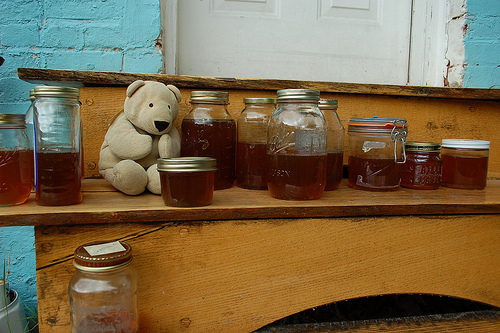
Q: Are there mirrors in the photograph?
A: No, there are no mirrors.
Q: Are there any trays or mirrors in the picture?
A: No, there are no mirrors or trays.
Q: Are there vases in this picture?
A: No, there are no vases.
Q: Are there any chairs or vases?
A: No, there are no vases or chairs.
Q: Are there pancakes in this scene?
A: No, there are no pancakes.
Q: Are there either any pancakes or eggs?
A: No, there are no pancakes or eggs.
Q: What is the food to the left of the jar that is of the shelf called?
A: The food is honey.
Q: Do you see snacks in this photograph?
A: No, there are no snacks.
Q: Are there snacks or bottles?
A: No, there are no snacks or bottles.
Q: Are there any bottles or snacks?
A: No, there are no snacks or bottles.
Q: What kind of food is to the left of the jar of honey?
A: The food is honey.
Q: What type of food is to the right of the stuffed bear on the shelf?
A: The food is honey.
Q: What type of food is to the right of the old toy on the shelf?
A: The food is honey.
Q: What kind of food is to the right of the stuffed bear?
A: The food is honey.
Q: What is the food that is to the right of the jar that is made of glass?
A: The food is honey.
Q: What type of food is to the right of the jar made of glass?
A: The food is honey.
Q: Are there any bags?
A: No, there are no bags.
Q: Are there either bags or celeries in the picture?
A: No, there are no bags or celeries.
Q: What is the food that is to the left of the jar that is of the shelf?
A: The food is honey.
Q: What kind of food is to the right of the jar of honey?
A: The food is honey.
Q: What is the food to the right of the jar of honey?
A: The food is honey.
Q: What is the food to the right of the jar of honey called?
A: The food is honey.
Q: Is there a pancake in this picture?
A: No, there are no pancakes.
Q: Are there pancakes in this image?
A: No, there are no pancakes.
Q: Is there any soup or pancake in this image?
A: No, there are no pancakes or soup.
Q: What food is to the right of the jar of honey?
A: The food is honey.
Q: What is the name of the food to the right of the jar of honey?
A: The food is honey.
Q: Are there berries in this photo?
A: No, there are no berries.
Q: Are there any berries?
A: No, there are no berries.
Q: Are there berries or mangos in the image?
A: No, there are no berries or mangos.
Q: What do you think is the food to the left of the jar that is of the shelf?
A: The food is honey.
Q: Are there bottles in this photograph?
A: No, there are no bottles.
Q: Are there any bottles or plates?
A: No, there are no bottles or plates.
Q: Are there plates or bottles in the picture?
A: No, there are no bottles or plates.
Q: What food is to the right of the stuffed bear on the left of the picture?
A: The food is honey.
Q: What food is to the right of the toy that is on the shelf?
A: The food is honey.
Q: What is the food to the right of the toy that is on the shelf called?
A: The food is honey.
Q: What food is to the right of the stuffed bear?
A: The food is honey.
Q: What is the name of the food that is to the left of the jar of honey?
A: The food is honey.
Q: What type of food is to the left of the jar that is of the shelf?
A: The food is honey.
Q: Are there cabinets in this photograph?
A: No, there are no cabinets.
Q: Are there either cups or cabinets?
A: No, there are no cabinets or cups.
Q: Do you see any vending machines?
A: No, there are no vending machines.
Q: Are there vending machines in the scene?
A: No, there are no vending machines.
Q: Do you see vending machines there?
A: No, there are no vending machines.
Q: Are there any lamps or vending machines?
A: No, there are no vending machines or lamps.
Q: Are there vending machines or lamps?
A: No, there are no vending machines or lamps.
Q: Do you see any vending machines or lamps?
A: No, there are no vending machines or lamps.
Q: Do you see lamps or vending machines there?
A: No, there are no vending machines or lamps.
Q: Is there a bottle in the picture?
A: No, there are no bottles.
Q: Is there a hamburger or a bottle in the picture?
A: No, there are no bottles or hamburgers.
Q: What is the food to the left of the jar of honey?
A: The food is honey.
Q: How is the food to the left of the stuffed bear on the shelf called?
A: The food is honey.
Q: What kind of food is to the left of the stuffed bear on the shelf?
A: The food is honey.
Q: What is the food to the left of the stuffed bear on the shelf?
A: The food is honey.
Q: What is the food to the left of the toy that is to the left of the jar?
A: The food is honey.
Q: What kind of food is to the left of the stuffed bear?
A: The food is honey.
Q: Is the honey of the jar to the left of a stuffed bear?
A: Yes, the honey is to the left of a stuffed bear.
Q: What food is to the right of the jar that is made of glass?
A: The food is honey.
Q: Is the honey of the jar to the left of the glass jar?
A: No, the honey is to the right of the jar.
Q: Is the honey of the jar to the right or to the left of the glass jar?
A: The honey is to the right of the jar.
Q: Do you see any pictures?
A: No, there are no pictures.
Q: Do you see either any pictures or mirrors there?
A: No, there are no pictures or mirrors.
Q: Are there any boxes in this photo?
A: No, there are no boxes.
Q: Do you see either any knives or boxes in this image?
A: No, there are no boxes or knives.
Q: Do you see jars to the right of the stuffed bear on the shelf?
A: Yes, there is a jar to the right of the stuffed bear.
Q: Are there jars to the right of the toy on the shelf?
A: Yes, there is a jar to the right of the stuffed bear.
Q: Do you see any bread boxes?
A: No, there are no bread boxes.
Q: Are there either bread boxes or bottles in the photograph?
A: No, there are no bread boxes or bottles.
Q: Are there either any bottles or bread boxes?
A: No, there are no bread boxes or bottles.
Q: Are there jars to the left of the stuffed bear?
A: Yes, there is a jar to the left of the stuffed bear.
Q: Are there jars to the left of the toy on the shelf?
A: Yes, there is a jar to the left of the stuffed bear.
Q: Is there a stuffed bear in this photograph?
A: Yes, there is a stuffed bear.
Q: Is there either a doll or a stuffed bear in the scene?
A: Yes, there is a stuffed bear.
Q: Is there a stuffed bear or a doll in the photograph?
A: Yes, there is a stuffed bear.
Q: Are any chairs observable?
A: No, there are no chairs.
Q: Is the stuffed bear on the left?
A: Yes, the stuffed bear is on the left of the image.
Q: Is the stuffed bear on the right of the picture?
A: No, the stuffed bear is on the left of the image.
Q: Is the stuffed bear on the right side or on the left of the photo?
A: The stuffed bear is on the left of the image.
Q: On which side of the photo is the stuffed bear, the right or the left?
A: The stuffed bear is on the left of the image.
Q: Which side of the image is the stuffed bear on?
A: The stuffed bear is on the left of the image.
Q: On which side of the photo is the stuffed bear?
A: The stuffed bear is on the left of the image.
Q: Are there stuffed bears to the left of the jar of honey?
A: Yes, there is a stuffed bear to the left of the jar.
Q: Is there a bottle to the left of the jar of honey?
A: No, there is a stuffed bear to the left of the jar.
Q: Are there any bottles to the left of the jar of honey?
A: No, there is a stuffed bear to the left of the jar.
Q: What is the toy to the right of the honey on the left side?
A: The toy is a stuffed bear.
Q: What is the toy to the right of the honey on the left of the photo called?
A: The toy is a stuffed bear.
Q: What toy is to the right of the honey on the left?
A: The toy is a stuffed bear.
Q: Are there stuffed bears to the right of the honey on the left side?
A: Yes, there is a stuffed bear to the right of the honey.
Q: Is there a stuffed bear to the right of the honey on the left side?
A: Yes, there is a stuffed bear to the right of the honey.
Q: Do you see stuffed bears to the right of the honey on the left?
A: Yes, there is a stuffed bear to the right of the honey.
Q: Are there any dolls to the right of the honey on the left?
A: No, there is a stuffed bear to the right of the honey.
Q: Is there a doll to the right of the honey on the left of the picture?
A: No, there is a stuffed bear to the right of the honey.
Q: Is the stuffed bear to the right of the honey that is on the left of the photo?
A: Yes, the stuffed bear is to the right of the honey.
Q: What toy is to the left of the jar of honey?
A: The toy is a stuffed bear.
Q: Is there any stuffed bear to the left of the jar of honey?
A: Yes, there is a stuffed bear to the left of the jar.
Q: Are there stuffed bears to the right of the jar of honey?
A: Yes, there is a stuffed bear to the right of the jar.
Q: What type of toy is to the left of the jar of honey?
A: The toy is a stuffed bear.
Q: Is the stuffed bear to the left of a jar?
A: Yes, the stuffed bear is to the left of a jar.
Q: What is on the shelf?
A: The stuffed bear is on the shelf.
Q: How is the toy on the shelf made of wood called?
A: The toy is a stuffed bear.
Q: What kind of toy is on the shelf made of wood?
A: The toy is a stuffed bear.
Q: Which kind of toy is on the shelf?
A: The toy is a stuffed bear.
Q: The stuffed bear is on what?
A: The stuffed bear is on the shelf.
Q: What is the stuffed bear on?
A: The stuffed bear is on the shelf.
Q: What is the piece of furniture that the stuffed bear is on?
A: The piece of furniture is a shelf.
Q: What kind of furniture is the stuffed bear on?
A: The stuffed bear is on the shelf.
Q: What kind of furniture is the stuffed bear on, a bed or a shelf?
A: The stuffed bear is on a shelf.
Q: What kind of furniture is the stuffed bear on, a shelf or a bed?
A: The stuffed bear is on a shelf.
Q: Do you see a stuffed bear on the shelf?
A: Yes, there is a stuffed bear on the shelf.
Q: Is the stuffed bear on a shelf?
A: Yes, the stuffed bear is on a shelf.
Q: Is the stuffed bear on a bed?
A: No, the stuffed bear is on a shelf.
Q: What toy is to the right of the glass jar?
A: The toy is a stuffed bear.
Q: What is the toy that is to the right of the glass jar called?
A: The toy is a stuffed bear.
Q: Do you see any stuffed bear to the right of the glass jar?
A: Yes, there is a stuffed bear to the right of the jar.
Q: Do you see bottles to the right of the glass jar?
A: No, there is a stuffed bear to the right of the jar.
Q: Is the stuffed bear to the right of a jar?
A: Yes, the stuffed bear is to the right of a jar.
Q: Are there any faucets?
A: No, there are no faucets.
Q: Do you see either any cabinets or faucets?
A: No, there are no faucets or cabinets.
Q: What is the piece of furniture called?
A: The piece of furniture is a shelf.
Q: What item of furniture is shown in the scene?
A: The piece of furniture is a shelf.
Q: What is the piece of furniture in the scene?
A: The piece of furniture is a shelf.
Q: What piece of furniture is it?
A: The piece of furniture is a shelf.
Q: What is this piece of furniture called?
A: That is a shelf.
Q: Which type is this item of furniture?
A: That is a shelf.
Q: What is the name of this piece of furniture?
A: That is a shelf.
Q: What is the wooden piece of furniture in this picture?
A: The piece of furniture is a shelf.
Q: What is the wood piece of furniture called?
A: The piece of furniture is a shelf.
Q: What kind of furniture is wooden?
A: The furniture is a shelf.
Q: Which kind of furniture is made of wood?
A: The furniture is a shelf.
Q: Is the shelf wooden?
A: Yes, the shelf is wooden.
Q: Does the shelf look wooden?
A: Yes, the shelf is wooden.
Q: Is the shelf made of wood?
A: Yes, the shelf is made of wood.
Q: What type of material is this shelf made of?
A: The shelf is made of wood.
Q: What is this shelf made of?
A: The shelf is made of wood.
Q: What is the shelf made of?
A: The shelf is made of wood.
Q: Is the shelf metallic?
A: No, the shelf is wooden.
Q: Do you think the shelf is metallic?
A: No, the shelf is wooden.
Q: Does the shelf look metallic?
A: No, the shelf is wooden.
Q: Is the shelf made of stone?
A: No, the shelf is made of wood.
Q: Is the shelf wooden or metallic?
A: The shelf is wooden.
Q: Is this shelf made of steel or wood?
A: The shelf is made of wood.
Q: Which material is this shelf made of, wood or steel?
A: The shelf is made of wood.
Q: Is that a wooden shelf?
A: Yes, that is a wooden shelf.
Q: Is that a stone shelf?
A: No, that is a wooden shelf.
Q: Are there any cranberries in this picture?
A: No, there are no cranberries.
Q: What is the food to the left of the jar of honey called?
A: The food is honey.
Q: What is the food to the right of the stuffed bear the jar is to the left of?
A: The food is honey.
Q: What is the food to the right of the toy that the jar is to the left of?
A: The food is honey.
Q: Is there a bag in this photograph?
A: No, there are no bags.